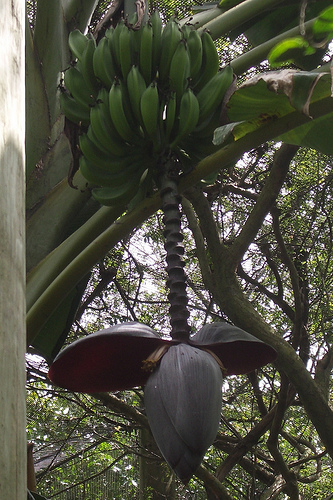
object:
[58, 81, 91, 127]
bananas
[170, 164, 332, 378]
branch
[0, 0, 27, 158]
sun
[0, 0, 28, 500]
wood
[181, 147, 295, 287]
shadow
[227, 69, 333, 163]
leaves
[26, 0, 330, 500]
tree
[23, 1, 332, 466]
sky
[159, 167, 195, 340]
stem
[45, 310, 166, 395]
petals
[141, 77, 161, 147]
banana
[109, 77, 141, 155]
banana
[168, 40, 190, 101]
banana